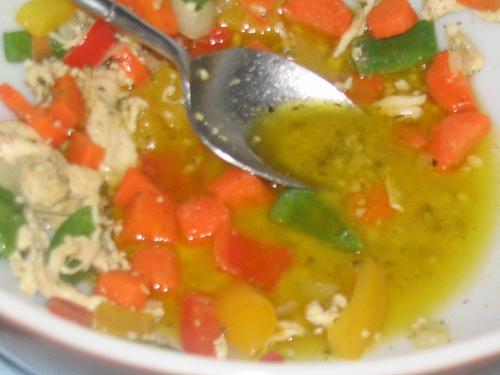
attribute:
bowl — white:
[4, 254, 488, 374]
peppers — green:
[341, 22, 447, 79]